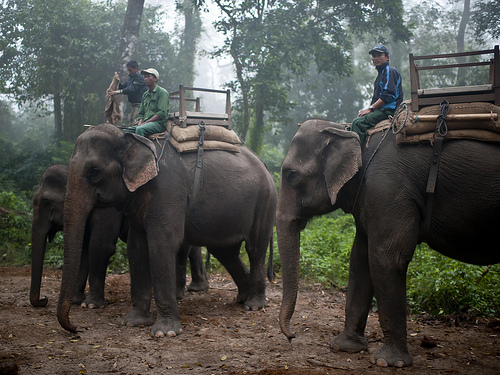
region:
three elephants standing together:
[0, 118, 419, 279]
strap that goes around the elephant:
[186, 106, 214, 246]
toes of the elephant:
[151, 332, 231, 360]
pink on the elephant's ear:
[118, 153, 170, 195]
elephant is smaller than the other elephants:
[13, 165, 80, 332]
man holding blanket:
[102, 68, 144, 133]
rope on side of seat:
[431, 97, 460, 149]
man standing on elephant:
[120, 50, 150, 127]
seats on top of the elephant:
[166, 76, 244, 158]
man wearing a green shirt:
[141, 93, 183, 131]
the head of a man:
[366, 37, 393, 68]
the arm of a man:
[369, 65, 397, 111]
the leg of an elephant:
[368, 212, 420, 344]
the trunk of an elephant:
[268, 185, 313, 350]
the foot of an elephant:
[368, 339, 420, 374]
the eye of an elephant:
[83, 161, 107, 184]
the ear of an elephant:
[115, 127, 170, 197]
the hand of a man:
[355, 102, 374, 121]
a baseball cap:
[365, 37, 395, 57]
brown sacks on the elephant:
[163, 115, 245, 160]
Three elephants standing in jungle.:
[21, 118, 498, 373]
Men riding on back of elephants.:
[99, 54, 186, 146]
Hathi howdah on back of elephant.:
[400, 36, 497, 113]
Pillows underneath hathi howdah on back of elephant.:
[168, 123, 248, 155]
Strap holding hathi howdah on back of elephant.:
[411, 102, 458, 247]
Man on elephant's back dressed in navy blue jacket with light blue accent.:
[366, 61, 410, 111]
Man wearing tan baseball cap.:
[138, 63, 165, 82]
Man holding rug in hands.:
[95, 66, 127, 126]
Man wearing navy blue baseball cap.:
[358, 42, 390, 56]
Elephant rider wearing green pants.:
[122, 113, 166, 143]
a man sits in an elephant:
[258, 32, 495, 373]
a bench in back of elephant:
[400, 42, 498, 120]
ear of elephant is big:
[310, 121, 370, 209]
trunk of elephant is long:
[264, 205, 311, 345]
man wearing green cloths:
[122, 61, 177, 139]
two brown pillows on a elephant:
[164, 118, 248, 160]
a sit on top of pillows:
[164, 80, 242, 130]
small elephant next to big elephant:
[20, 160, 114, 317]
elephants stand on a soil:
[0, 267, 492, 374]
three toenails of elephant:
[147, 320, 188, 345]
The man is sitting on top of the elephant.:
[330, 39, 419, 154]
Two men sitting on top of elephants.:
[85, 68, 174, 162]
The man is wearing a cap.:
[356, 31, 396, 61]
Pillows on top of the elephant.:
[168, 121, 240, 163]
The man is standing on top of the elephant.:
[101, 63, 143, 111]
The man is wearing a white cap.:
[138, 56, 170, 96]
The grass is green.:
[296, 210, 471, 296]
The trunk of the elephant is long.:
[261, 193, 315, 352]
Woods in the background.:
[114, 11, 382, 128]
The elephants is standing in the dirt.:
[38, 162, 308, 342]